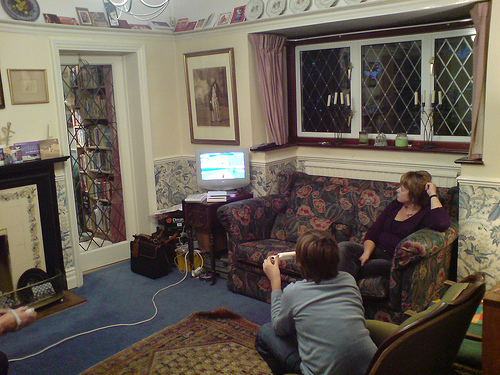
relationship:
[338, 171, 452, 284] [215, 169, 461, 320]
woman sitting on couch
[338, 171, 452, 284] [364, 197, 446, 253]
woman wearing shirt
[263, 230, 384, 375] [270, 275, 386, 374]
person wearing shirt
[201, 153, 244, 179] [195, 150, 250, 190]
screen of television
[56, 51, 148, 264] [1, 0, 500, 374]
door of room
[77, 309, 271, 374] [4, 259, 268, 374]
rug on floor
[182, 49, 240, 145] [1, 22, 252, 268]
picture hanging on wall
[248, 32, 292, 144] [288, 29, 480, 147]
curtains by window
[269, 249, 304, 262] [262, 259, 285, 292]
controller in hands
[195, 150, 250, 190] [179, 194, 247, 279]
television on table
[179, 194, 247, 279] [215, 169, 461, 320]
table by couch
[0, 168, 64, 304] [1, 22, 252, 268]
fireplace on wall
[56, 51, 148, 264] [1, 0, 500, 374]
door to room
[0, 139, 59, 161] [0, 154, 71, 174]
cards on mantle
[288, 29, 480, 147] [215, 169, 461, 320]
window over couch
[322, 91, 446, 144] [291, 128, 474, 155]
candles on window frame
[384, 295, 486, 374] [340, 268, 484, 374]
back of chair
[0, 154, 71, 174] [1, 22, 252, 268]
mantle on wall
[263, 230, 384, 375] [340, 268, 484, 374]
person sitting on chair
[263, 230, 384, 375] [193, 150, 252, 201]
person playing game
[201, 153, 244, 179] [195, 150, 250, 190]
moniter of computer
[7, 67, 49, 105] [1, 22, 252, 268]
plaque on wall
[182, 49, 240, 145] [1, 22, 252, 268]
picture on wall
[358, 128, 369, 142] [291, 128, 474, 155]
candle by window frame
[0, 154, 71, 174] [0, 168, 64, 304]
mantle of fireplace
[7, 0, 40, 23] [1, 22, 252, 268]
plate on wall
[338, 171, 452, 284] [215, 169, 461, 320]
woman on couch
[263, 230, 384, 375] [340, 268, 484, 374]
person on chair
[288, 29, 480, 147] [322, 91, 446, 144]
window with candles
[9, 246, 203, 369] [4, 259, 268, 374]
cord on floor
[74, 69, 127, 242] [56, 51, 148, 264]
book cases by door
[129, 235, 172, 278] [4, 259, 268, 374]
bag on floor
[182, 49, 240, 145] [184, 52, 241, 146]
picture in frame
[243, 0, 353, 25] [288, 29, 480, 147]
dishes above window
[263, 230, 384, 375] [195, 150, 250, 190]
person watching television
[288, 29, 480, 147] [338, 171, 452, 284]
window behind woman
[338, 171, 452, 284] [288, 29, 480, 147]
woman sitting near window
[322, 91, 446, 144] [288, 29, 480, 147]
candles near window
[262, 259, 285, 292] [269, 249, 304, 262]
hands holding controller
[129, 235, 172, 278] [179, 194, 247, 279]
bag next to table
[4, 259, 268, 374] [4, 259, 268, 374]
chord on floor